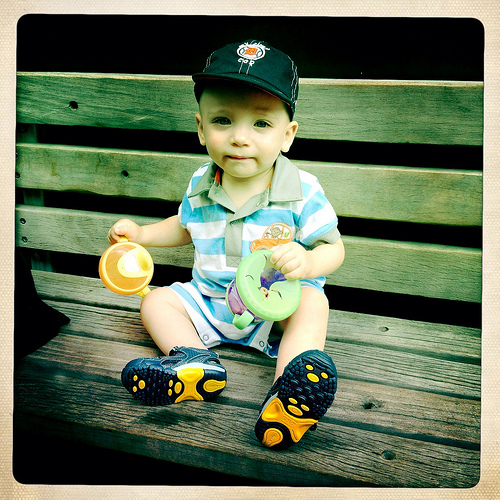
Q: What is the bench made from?
A: Wood.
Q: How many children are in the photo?
A: One.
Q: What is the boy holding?
A: Cups.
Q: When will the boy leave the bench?
A: When his mama comes and gets him off of the bench.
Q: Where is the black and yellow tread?
A: On the bottom of the boy's shoe.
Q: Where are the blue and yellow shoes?
A: On the baby.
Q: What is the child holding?
A: A purple sippy cup.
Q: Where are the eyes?
A: On the face of the baby.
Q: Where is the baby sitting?
A: On a bench.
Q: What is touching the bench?
A: The legs and shoes of the baby.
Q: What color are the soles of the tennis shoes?
A: Yellow and black.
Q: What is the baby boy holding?
A: Toys.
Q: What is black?
A: Hat.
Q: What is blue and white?
A: Boy's shirt.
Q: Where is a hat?
A: On boy's head.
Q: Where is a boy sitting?
A: On a bench.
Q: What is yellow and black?
A: Shoes.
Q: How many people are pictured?
A: One.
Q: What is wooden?
A: The bench.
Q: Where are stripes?
A: On boy's shirt.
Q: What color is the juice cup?
A: Orange.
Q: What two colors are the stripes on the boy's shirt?
A: Blue and white.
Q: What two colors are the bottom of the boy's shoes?
A: Black and yellow.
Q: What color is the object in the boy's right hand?
A: Orange.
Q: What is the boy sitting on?
A: A bench.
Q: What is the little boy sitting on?
A: A bench.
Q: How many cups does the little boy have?
A: One.